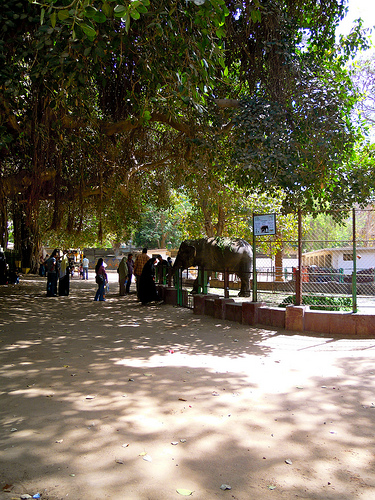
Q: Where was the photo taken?
A: The zoo.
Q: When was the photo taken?
A: Afternoon.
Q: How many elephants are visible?
A: One.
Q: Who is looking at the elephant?
A: The zoo visitors.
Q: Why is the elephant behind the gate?
A: Visitor safety.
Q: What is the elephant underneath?
A: Trees.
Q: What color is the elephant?
A: Gray.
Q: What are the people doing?
A: Looking at the elephant.